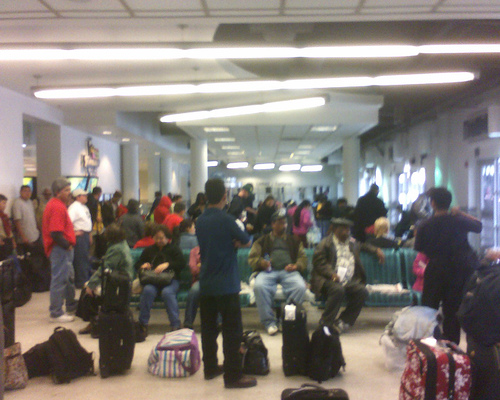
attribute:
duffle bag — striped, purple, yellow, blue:
[137, 325, 189, 367]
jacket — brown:
[297, 217, 388, 315]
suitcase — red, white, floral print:
[400, 335, 474, 399]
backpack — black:
[117, 310, 257, 397]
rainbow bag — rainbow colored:
[133, 314, 215, 382]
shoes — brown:
[201, 362, 258, 388]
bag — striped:
[148, 324, 203, 378]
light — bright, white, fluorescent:
[58, 58, 498, 98]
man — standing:
[39, 180, 75, 323]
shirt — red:
[40, 197, 75, 249]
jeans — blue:
[47, 241, 77, 318]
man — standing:
[186, 179, 261, 396]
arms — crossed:
[229, 220, 257, 247]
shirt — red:
[40, 196, 76, 258]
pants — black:
[190, 283, 248, 383]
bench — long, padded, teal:
[126, 247, 461, 298]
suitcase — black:
[307, 323, 346, 380]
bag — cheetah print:
[2, 343, 31, 391]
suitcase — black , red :
[385, 320, 484, 398]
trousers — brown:
[324, 280, 364, 337]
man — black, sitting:
[308, 210, 378, 331]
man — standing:
[197, 175, 258, 390]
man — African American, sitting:
[255, 203, 308, 281]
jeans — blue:
[253, 267, 313, 316]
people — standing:
[37, 190, 282, 292]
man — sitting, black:
[311, 216, 386, 334]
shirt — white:
[328, 236, 358, 286]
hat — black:
[329, 216, 357, 231]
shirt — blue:
[191, 206, 251, 302]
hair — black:
[203, 178, 227, 208]